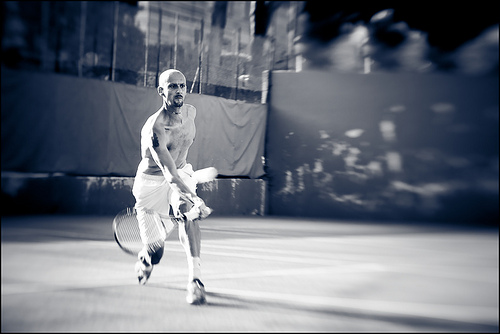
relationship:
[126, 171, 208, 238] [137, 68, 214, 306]
shorts worn by man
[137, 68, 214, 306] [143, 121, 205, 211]
man has arm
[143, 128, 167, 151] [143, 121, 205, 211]
tattoo on arm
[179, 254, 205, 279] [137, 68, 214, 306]
socks worn by man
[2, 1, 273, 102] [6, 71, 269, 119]
fence in background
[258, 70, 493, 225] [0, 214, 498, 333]
wall by tennis court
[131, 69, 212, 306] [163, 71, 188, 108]
man has face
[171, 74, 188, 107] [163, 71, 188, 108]
expression on face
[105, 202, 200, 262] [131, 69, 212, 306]
tennis racket held by man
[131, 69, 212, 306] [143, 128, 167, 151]
man has tattoo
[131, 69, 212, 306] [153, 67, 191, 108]
man has head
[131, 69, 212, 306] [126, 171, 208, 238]
man wears shorts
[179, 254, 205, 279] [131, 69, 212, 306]
socks on man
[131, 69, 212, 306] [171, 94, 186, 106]
man has beard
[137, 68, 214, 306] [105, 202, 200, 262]
man holding tennis racket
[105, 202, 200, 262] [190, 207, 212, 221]
tennis racket in handle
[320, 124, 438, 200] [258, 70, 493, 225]
markings on wall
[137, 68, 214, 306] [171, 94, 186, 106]
man has goatee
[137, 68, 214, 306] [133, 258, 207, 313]
man wearing sneakers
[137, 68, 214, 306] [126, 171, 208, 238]
man wearing shorts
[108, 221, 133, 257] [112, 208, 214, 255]
edge of tennis racket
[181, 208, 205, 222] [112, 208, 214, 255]
handle of tennis racket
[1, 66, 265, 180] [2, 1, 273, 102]
wind screen on fence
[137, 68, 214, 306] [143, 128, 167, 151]
man has tattoo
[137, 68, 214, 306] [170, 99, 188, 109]
man has goatee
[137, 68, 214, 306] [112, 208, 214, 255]
man playing tennis racket